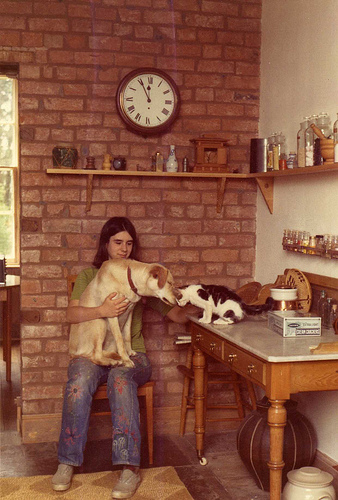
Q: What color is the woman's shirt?
A: Green.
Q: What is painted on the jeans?
A: Flowers.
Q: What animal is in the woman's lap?
A: Dog.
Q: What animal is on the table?
A: Cat.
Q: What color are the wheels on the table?
A: White.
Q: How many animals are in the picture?
A: Two.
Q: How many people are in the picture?
A: One.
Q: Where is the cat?
A: On the table.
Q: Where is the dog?
A: On the girl's lap.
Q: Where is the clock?
A: On the wall above the girl.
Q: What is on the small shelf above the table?
A: Spices.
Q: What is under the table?
A: A large striped vase.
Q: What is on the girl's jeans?
A: Flowers.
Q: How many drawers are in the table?
A: Two.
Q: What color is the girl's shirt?
A: Green.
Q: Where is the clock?
A: On the wall.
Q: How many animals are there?
A: Two.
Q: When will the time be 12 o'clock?
A: In five minutes.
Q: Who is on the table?
A: A cat.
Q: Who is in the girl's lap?
A: A dog.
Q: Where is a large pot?
A: Under the table.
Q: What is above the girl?
A: A shelf.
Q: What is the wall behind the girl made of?
A: Bricks.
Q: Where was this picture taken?
A: The house.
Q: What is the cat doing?
A: Sitting on the table.